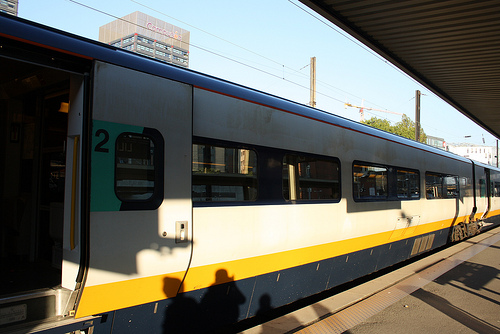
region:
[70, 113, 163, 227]
a green sign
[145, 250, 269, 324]
shadows on the side of the train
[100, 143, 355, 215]
a clear window on the train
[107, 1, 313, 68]
telephone wires in the sky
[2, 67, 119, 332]
open compartment of the train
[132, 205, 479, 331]
blue and yellow stripes on the train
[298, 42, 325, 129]
a wooden telephone pole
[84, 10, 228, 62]
a building tower in the sky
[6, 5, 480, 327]
a train at the train stop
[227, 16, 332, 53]
a baby blue sky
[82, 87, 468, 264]
Black, yellow and white train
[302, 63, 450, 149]
Powerlines behind the train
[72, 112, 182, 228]
Train numbered as the #2 train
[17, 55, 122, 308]
Train door open for people to board and get off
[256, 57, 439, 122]
Clear blue cloudless sky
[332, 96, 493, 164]
Buildings behind the train in the skyline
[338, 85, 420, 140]
Trees visible behind the train in the skyline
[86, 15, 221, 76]
Tall building visible behind the train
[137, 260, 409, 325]
Shadows of people standing on the platform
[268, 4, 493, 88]
Overhang of the train station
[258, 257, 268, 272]
the line is yellow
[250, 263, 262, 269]
the line is yellow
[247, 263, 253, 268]
the line is yellow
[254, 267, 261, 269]
the line is yellow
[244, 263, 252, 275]
the line is yellow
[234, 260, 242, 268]
the line is yellow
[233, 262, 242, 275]
the line is yellow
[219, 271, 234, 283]
the line is yellow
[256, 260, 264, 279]
the line is yellow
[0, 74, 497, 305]
A side view of a train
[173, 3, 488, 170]
The sky is clear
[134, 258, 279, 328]
People are casting shadows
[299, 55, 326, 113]
Wooden pole is in the background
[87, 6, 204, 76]
A building is in the background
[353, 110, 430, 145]
A tree is in the background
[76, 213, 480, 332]
Train has a yellow and blue stripe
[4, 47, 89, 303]
Train door is open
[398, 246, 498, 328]
Objects are casting a shadow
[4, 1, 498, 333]
Photo was taken outside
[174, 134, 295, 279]
a train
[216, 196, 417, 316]
a train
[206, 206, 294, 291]
a train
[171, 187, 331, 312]
a train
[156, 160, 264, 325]
a train